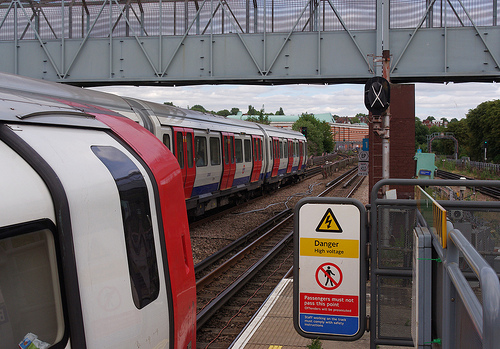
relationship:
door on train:
[221, 128, 236, 188] [128, 96, 310, 216]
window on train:
[163, 131, 308, 170] [0, 70, 310, 216]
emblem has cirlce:
[314, 258, 343, 288] [315, 257, 344, 292]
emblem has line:
[314, 258, 343, 288] [317, 266, 340, 285]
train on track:
[11, 80, 326, 219] [210, 239, 281, 327]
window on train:
[266, 144, 285, 159] [191, 115, 302, 175]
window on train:
[88, 143, 159, 310] [1, 87, 319, 343]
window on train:
[163, 131, 308, 170] [1, 87, 319, 343]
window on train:
[163, 131, 308, 170] [2, 68, 370, 208]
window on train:
[11, 229, 113, 340] [19, 86, 339, 284]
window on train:
[163, 131, 308, 170] [22, 78, 312, 222]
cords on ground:
[237, 178, 324, 218] [218, 297, 296, 345]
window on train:
[163, 131, 308, 170] [2, 69, 314, 199]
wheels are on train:
[175, 176, 300, 248] [57, 80, 387, 233]